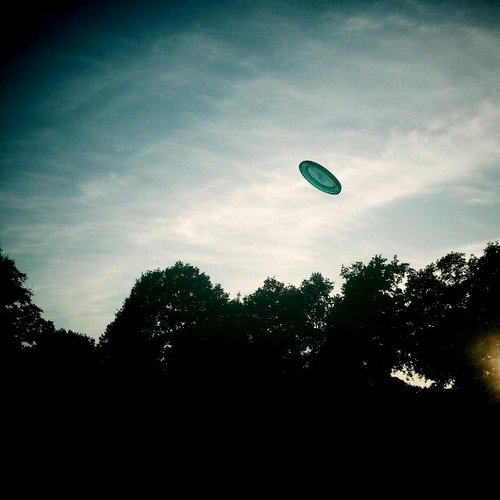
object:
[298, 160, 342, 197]
frisbee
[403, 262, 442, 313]
leaf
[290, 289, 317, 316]
leaf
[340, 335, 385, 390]
leaf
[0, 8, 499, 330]
cloud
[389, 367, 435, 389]
break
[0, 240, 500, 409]
tree line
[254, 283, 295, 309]
leaves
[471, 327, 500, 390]
glimmer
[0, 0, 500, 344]
sky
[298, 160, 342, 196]
circle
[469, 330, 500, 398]
sun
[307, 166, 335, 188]
circle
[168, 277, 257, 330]
leaves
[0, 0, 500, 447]
air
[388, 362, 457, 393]
light shining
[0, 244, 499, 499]
trees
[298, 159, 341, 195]
shape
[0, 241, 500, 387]
outline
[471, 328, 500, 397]
light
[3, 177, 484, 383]
background